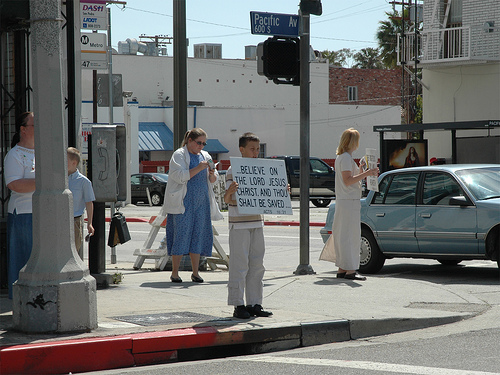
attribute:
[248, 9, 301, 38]
street sign —  blue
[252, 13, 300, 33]
letters —  white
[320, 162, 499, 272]
sedan — light blue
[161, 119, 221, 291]
woman — Middle Aged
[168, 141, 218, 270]
dress — blue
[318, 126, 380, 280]
woman — blonde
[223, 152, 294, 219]
sign — religious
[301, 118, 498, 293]
car — blue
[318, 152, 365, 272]
dress — white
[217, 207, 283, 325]
pants — tan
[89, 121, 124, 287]
phone booth — metal, silver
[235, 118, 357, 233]
truck — black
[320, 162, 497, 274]
automobile — blue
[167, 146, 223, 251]
dress — blue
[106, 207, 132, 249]
phone book —  black